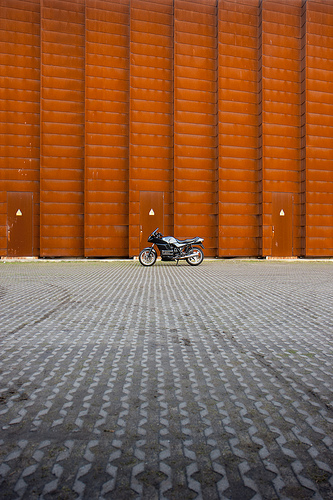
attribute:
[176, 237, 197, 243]
seat — black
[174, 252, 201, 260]
exhaust — silver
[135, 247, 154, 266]
wheels — black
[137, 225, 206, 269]
motorcycle — black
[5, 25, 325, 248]
wall — rusty, metal, section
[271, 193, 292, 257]
door — rusty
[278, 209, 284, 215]
symbol — white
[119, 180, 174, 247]
door — rusty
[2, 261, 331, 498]
ground — grey, patterned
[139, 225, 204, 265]
bike — motor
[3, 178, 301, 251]
doors — rusty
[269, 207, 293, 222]
symbol — white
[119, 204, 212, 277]
bike — motor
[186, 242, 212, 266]
wheel — back, black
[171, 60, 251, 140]
walls — orange, tall